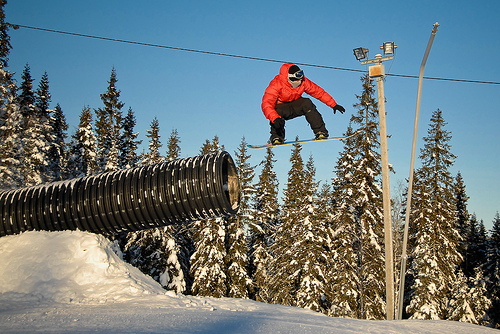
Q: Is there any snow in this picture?
A: Yes, there is snow.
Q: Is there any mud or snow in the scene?
A: Yes, there is snow.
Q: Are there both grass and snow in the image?
A: No, there is snow but no grass.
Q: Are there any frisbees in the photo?
A: No, there are no frisbees.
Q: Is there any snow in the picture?
A: Yes, there is snow.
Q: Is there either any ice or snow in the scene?
A: Yes, there is snow.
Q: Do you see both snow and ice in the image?
A: No, there is snow but no ice.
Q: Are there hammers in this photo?
A: No, there are no hammers.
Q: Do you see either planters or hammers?
A: No, there are no hammers or planters.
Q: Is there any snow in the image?
A: Yes, there is snow.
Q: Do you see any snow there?
A: Yes, there is snow.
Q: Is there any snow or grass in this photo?
A: Yes, there is snow.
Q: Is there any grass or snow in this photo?
A: Yes, there is snow.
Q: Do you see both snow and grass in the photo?
A: No, there is snow but no grass.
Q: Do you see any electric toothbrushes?
A: No, there are no electric toothbrushes.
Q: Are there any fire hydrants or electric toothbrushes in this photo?
A: No, there are no electric toothbrushes or fire hydrants.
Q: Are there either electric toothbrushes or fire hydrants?
A: No, there are no electric toothbrushes or fire hydrants.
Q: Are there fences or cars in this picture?
A: No, there are no fences or cars.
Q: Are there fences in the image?
A: No, there are no fences.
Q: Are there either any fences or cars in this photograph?
A: No, there are no fences or cars.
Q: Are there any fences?
A: No, there are no fences.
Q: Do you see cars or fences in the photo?
A: No, there are no fences or cars.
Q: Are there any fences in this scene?
A: No, there are no fences.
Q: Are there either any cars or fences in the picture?
A: No, there are no fences or cars.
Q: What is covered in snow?
A: The tree is covered in snow.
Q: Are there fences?
A: No, there are no fences.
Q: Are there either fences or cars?
A: No, there are no fences or cars.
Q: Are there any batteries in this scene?
A: No, there are no batteries.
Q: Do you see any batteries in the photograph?
A: No, there are no batteries.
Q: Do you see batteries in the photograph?
A: No, there are no batteries.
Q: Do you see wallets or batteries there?
A: No, there are no batteries or wallets.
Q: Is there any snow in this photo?
A: Yes, there is snow.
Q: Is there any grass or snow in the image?
A: Yes, there is snow.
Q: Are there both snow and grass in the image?
A: No, there is snow but no grass.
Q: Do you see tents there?
A: No, there are no tents.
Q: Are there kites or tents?
A: No, there are no tents or kites.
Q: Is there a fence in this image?
A: No, there are no fences.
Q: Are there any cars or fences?
A: No, there are no fences or cars.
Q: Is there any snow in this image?
A: Yes, there is snow.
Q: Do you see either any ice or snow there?
A: Yes, there is snow.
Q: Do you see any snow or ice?
A: Yes, there is snow.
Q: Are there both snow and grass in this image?
A: No, there is snow but no grass.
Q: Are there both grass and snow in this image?
A: No, there is snow but no grass.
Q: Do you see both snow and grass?
A: No, there is snow but no grass.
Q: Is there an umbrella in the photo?
A: No, there are no umbrellas.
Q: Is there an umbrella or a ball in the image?
A: No, there are no umbrellas or balls.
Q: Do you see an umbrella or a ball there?
A: No, there are no umbrellas or balls.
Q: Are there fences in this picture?
A: No, there are no fences.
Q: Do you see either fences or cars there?
A: No, there are no fences or cars.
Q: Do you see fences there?
A: No, there are no fences.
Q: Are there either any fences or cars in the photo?
A: No, there are no fences or cars.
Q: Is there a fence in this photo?
A: No, there are no fences.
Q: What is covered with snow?
A: The tree is covered with snow.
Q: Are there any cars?
A: No, there are no cars.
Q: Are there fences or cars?
A: No, there are no cars or fences.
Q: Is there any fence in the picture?
A: No, there are no fences.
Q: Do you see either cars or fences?
A: No, there are no fences or cars.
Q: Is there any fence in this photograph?
A: No, there are no fences.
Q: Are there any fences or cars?
A: No, there are no fences or cars.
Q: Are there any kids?
A: No, there are no kids.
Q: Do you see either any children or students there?
A: No, there are no children or students.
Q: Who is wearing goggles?
A: The man is wearing goggles.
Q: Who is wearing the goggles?
A: The man is wearing goggles.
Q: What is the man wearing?
A: The man is wearing goggles.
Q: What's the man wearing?
A: The man is wearing goggles.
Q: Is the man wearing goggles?
A: Yes, the man is wearing goggles.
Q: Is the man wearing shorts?
A: No, the man is wearing goggles.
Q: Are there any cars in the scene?
A: No, there are no cars.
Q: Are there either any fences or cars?
A: No, there are no cars or fences.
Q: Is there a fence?
A: No, there are no fences.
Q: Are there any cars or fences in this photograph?
A: No, there are no fences or cars.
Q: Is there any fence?
A: No, there are no fences.